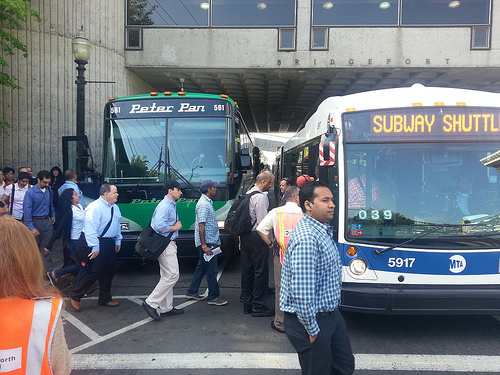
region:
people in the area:
[25, 35, 462, 332]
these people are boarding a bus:
[20, 81, 482, 321]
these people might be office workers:
[23, 165, 488, 317]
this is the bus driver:
[417, 152, 496, 226]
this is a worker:
[0, 209, 89, 374]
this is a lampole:
[55, 23, 120, 187]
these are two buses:
[97, 55, 497, 215]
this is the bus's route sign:
[332, 94, 498, 163]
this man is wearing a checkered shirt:
[270, 162, 366, 369]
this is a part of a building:
[128, 6, 499, 93]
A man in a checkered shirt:
[274, 209, 352, 329]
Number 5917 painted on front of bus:
[381, 251, 421, 283]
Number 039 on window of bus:
[349, 201, 405, 235]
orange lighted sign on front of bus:
[366, 105, 463, 143]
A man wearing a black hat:
[156, 171, 188, 202]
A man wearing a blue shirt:
[145, 191, 186, 251]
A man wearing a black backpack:
[218, 189, 260, 251]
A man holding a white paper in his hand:
[195, 236, 233, 274]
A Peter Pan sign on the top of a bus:
[127, 93, 217, 125]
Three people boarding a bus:
[133, 168, 279, 322]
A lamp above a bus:
[70, 27, 90, 57]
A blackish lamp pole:
[75, 63, 82, 133]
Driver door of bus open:
[62, 136, 90, 169]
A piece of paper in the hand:
[205, 248, 217, 255]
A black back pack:
[237, 203, 249, 230]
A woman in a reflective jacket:
[2, 300, 47, 345]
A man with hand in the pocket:
[303, 332, 318, 343]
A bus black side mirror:
[238, 146, 251, 168]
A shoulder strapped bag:
[141, 235, 158, 254]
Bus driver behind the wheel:
[453, 175, 477, 212]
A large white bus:
[270, 91, 498, 308]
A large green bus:
[108, 95, 265, 256]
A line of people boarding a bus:
[2, 168, 313, 309]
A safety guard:
[0, 216, 75, 373]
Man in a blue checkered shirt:
[280, 179, 357, 371]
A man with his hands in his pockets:
[277, 182, 359, 372]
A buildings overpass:
[125, 0, 497, 65]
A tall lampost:
[68, 23, 90, 180]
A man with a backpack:
[219, 167, 277, 313]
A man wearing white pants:
[133, 179, 183, 316]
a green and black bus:
[103, 94, 256, 265]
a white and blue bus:
[269, 81, 499, 312]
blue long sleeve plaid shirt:
[278, 213, 345, 334]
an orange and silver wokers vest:
[1, 295, 62, 373]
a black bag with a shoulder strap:
[79, 208, 116, 253]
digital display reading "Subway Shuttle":
[348, 113, 499, 142]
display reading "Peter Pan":
[105, 101, 230, 119]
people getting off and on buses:
[0, 163, 308, 318]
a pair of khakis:
[148, 241, 180, 313]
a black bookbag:
[226, 188, 264, 223]